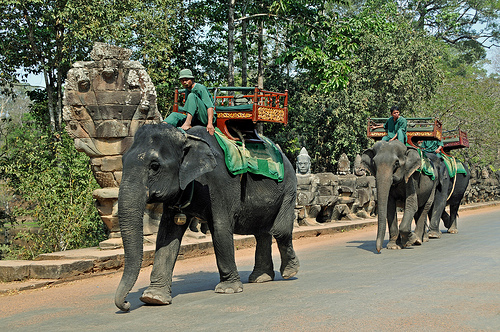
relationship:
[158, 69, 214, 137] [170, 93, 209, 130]
man wearing green pants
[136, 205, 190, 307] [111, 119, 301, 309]
leg of elephant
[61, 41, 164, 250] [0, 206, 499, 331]
statue on side of ground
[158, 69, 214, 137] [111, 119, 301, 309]
man on top of elephant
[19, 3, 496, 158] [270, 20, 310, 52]
trees with leaves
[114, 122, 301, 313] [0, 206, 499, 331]
elephant transports on ground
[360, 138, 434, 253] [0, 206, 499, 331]
elephant transports on ground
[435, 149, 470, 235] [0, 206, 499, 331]
elephant transports on ground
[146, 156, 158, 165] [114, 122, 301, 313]
eye of elephant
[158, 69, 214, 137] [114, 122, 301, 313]
man on back of elephant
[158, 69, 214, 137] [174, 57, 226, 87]
man wearing hat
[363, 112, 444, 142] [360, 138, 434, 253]
wooden cart on back of elephant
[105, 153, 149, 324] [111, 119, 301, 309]
trunk of elephant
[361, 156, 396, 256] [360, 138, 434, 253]
trunk of elephant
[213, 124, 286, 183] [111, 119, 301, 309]
blanket on back of elephant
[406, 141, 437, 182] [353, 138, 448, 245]
blanket on back of elephant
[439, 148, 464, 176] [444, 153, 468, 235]
green blanket on back of elephant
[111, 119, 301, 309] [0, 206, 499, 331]
elephant walking in ground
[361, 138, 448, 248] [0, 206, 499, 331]
elephant walking in ground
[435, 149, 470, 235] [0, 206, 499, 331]
elephant walking in ground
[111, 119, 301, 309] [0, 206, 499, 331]
elephant on ground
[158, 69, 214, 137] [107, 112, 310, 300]
man riding elephant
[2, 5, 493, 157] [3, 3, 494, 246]
leaves on trees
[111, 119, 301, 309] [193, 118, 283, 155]
elephant has back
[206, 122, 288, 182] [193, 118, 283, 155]
blanket on back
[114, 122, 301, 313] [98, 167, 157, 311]
elephant has trunk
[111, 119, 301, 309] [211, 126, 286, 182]
elephant wearing blanket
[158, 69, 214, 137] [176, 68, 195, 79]
man wearing hat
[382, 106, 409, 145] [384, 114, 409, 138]
man wearing shirt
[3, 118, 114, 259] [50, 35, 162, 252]
trees next to statue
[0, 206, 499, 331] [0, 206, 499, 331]
ground on ground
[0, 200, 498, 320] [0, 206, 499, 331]
dirt on ground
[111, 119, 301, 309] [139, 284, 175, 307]
elephant has foot